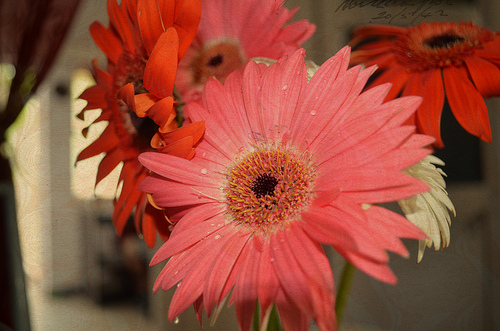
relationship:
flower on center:
[347, 17, 498, 149] [419, 26, 463, 51]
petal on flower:
[420, 66, 443, 145] [390, 27, 491, 127]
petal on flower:
[435, 57, 482, 139] [390, 27, 491, 127]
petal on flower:
[369, 59, 402, 94] [390, 27, 491, 127]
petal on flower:
[200, 222, 245, 309] [156, 66, 428, 320]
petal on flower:
[141, 31, 174, 111] [84, 5, 195, 250]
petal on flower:
[141, 31, 174, 111] [170, 2, 314, 104]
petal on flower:
[367, 63, 406, 103] [109, 50, 469, 327]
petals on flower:
[139, 23, 185, 103] [64, 5, 219, 250]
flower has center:
[135, 61, 429, 328] [227, 144, 309, 224]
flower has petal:
[135, 44, 437, 331] [257, 237, 345, 322]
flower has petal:
[135, 44, 437, 331] [410, 179, 453, 249]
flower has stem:
[93, 2, 484, 326] [330, 262, 350, 329]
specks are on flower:
[359, 198, 373, 211] [120, 36, 444, 328]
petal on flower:
[295, 61, 360, 150] [135, 61, 429, 328]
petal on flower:
[319, 150, 431, 221] [129, 40, 465, 322]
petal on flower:
[271, 239, 339, 309] [135, 61, 429, 328]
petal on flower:
[136, 55, 425, 329] [135, 44, 437, 331]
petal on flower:
[311, 49, 337, 159] [109, 50, 469, 327]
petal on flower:
[270, 61, 298, 150] [135, 61, 429, 328]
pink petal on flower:
[137, 149, 230, 192] [135, 61, 429, 328]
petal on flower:
[147, 30, 177, 103] [135, 61, 429, 328]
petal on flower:
[416, 64, 443, 147] [335, 18, 497, 328]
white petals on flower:
[405, 156, 457, 263] [301, 62, 459, 230]